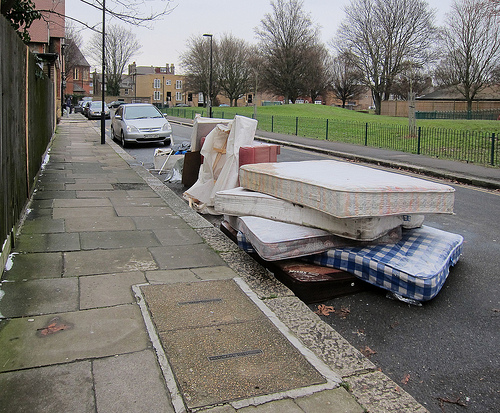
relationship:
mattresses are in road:
[213, 153, 468, 307] [91, 108, 498, 408]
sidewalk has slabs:
[0, 108, 428, 412] [3, 104, 376, 413]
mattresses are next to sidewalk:
[213, 153, 468, 307] [0, 108, 428, 412]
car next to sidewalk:
[110, 102, 172, 146] [0, 108, 428, 412]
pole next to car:
[100, 1, 107, 144] [110, 102, 172, 146]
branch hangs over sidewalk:
[25, 7, 110, 38] [0, 108, 428, 412]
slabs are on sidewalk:
[3, 104, 376, 413] [0, 108, 428, 412]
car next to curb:
[110, 102, 172, 146] [89, 121, 430, 411]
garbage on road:
[151, 113, 281, 213] [91, 108, 498, 408]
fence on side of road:
[156, 101, 497, 169] [91, 108, 498, 408]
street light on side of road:
[202, 32, 214, 115] [91, 108, 498, 408]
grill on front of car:
[125, 126, 172, 142] [110, 102, 172, 146]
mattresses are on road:
[213, 153, 468, 307] [91, 108, 498, 408]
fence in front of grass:
[156, 101, 497, 169] [158, 99, 497, 166]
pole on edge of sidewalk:
[100, 1, 107, 144] [0, 108, 428, 412]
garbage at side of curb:
[151, 113, 281, 213] [89, 121, 430, 411]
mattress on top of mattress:
[236, 157, 457, 219] [212, 184, 423, 241]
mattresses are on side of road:
[213, 153, 468, 307] [91, 108, 498, 408]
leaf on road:
[315, 302, 334, 318] [91, 108, 498, 408]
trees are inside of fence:
[183, 0, 498, 120] [156, 101, 497, 169]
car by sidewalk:
[110, 102, 172, 146] [0, 108, 428, 412]